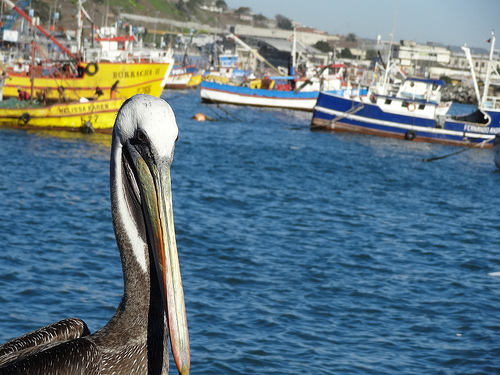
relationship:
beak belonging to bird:
[128, 142, 193, 372] [3, 94, 192, 375]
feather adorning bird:
[60, 320, 75, 336] [2, 92, 192, 372]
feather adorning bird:
[34, 330, 53, 341] [2, 92, 192, 372]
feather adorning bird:
[15, 338, 35, 349] [2, 92, 192, 372]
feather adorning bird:
[132, 344, 142, 356] [2, 92, 192, 372]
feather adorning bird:
[97, 350, 116, 357] [2, 92, 192, 372]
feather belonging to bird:
[34, 358, 54, 372] [2, 92, 192, 372]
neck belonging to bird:
[109, 131, 169, 340] [3, 94, 192, 375]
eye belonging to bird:
[135, 128, 147, 143] [2, 92, 192, 372]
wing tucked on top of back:
[1, 315, 88, 365] [1, 330, 102, 372]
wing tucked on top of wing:
[1, 315, 88, 365] [1, 315, 88, 365]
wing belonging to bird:
[1, 315, 88, 365] [2, 92, 192, 372]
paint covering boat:
[1, 94, 128, 137] [2, 94, 128, 136]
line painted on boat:
[1, 76, 165, 91] [2, 1, 172, 101]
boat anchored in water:
[308, 29, 483, 149] [1, 85, 484, 371]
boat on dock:
[308, 32, 497, 149] [269, 47, 451, 131]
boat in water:
[0, 20, 171, 108] [16, 128, 396, 308]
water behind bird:
[0, 85, 498, 371] [3, 77, 276, 370]